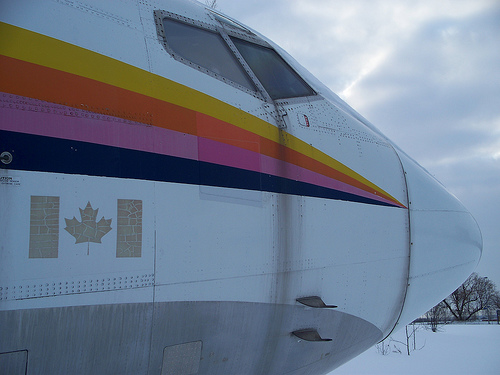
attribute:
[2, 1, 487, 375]
plane — large, white, big, coloured, sharp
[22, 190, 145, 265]
flag — faded, canadian, sticker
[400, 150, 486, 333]
nose — white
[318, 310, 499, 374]
snow — white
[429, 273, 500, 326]
tree — leafless, far, short, green, growing, small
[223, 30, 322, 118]
window — glass, glaass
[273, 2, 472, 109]
clouds — thick, white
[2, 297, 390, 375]
bottom — gray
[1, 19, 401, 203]
stripe — yellow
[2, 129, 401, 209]
stripe — navy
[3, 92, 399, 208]
stripe — pink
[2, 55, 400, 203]
stripe — orange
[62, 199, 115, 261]
leaf — maple